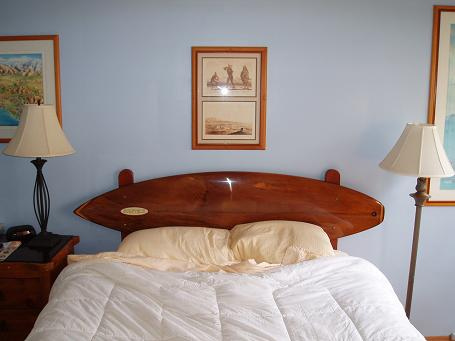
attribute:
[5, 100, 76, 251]
lamp — very pretty, black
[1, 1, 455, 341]
wall — blue, part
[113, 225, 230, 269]
pillow — cream colored, cream, partial, peach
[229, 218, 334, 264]
pillow — cream colored, cream, partial, peach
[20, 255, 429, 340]
comforter — white, cloth, puffy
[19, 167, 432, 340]
bed — well spread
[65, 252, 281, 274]
sheet — partial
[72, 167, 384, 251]
headboard — wood, shaped like surfboar, wooden, surfboard shaped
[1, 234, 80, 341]
nightstand — partial, brown, wooden, wood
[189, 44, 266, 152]
frame — wood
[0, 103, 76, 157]
lamp shade — ivory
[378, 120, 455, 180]
lamp shade — ivory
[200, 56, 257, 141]
artwork — framed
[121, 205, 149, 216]
sticker — small, gold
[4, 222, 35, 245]
alarm clock — black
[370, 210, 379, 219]
circle — black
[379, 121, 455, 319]
floor lamp — floor lamp